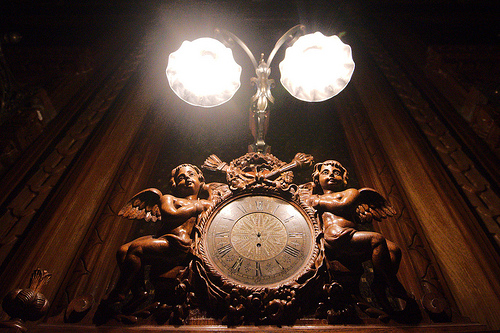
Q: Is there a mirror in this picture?
A: No, there are no mirrors.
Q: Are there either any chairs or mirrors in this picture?
A: No, there are no mirrors or chairs.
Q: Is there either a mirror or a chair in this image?
A: No, there are no mirrors or chairs.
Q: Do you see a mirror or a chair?
A: No, there are no mirrors or chairs.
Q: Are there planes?
A: No, there are no planes.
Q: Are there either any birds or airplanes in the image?
A: No, there are no airplanes or birds.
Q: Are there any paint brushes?
A: No, there are no paint brushes.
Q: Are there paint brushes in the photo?
A: No, there are no paint brushes.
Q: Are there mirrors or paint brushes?
A: No, there are no paint brushes or mirrors.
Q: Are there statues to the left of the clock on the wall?
A: Yes, there is a statue to the left of the clock.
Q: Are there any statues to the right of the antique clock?
A: No, the statue is to the left of the clock.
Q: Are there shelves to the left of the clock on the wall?
A: No, there is a statue to the left of the clock.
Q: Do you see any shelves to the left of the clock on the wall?
A: No, there is a statue to the left of the clock.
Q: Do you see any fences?
A: No, there are no fences.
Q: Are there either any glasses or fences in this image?
A: No, there are no fences or glasses.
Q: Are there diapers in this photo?
A: No, there are no diapers.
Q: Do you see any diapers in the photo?
A: No, there are no diapers.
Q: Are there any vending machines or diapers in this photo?
A: No, there are no diapers or vending machines.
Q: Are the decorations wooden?
A: Yes, the decorations are wooden.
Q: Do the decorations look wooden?
A: Yes, the decorations are wooden.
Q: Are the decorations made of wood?
A: Yes, the decorations are made of wood.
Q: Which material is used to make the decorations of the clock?
A: The decorations are made of wood.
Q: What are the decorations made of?
A: The decorations are made of wood.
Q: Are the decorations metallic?
A: No, the decorations are wooden.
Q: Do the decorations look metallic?
A: No, the decorations are wooden.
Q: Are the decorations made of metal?
A: No, the decorations are made of wood.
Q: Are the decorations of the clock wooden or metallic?
A: The decorations are wooden.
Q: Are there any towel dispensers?
A: No, there are no towel dispensers.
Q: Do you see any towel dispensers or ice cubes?
A: No, there are no towel dispensers or ice cubes.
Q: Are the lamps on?
A: Yes, the lamps are on.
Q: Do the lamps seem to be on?
A: Yes, the lamps are on.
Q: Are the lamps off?
A: No, the lamps are on.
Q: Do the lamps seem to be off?
A: No, the lamps are on.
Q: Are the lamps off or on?
A: The lamps are on.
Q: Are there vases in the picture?
A: No, there are no vases.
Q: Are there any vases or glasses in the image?
A: No, there are no vases or glasses.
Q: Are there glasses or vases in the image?
A: No, there are no vases or glasses.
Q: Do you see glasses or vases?
A: No, there are no vases or glasses.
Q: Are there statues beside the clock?
A: Yes, there is a statue beside the clock.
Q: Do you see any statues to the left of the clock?
A: Yes, there is a statue to the left of the clock.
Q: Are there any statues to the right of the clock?
A: No, the statue is to the left of the clock.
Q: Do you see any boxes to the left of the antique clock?
A: No, there is a statue to the left of the clock.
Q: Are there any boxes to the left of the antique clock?
A: No, there is a statue to the left of the clock.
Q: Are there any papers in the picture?
A: No, there are no papers.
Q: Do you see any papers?
A: No, there are no papers.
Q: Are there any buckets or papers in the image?
A: No, there are no papers or buckets.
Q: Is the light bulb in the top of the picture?
A: Yes, the light bulb is in the top of the image.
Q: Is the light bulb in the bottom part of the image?
A: No, the light bulb is in the top of the image.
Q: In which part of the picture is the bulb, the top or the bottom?
A: The bulb is in the top of the image.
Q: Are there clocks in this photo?
A: Yes, there is a clock.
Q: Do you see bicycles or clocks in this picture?
A: Yes, there is a clock.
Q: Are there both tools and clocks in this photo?
A: No, there is a clock but no tools.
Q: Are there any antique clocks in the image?
A: Yes, there is an antique clock.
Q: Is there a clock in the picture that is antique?
A: Yes, there is a clock that is antique.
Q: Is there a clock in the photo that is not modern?
A: Yes, there is a antique clock.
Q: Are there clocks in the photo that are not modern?
A: Yes, there is a antique clock.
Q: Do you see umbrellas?
A: No, there are no umbrellas.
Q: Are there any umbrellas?
A: No, there are no umbrellas.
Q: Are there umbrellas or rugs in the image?
A: No, there are no umbrellas or rugs.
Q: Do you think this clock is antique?
A: Yes, the clock is antique.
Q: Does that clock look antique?
A: Yes, the clock is antique.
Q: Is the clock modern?
A: No, the clock is antique.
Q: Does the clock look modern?
A: No, the clock is antique.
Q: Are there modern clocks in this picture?
A: No, there is a clock but it is antique.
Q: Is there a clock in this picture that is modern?
A: No, there is a clock but it is antique.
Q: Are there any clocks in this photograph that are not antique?
A: No, there is a clock but it is antique.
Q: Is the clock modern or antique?
A: The clock is antique.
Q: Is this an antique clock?
A: Yes, this is an antique clock.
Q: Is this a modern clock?
A: No, this is an antique clock.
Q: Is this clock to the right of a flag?
A: No, the clock is to the right of a statue.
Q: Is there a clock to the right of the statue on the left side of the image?
A: Yes, there is a clock to the right of the statue.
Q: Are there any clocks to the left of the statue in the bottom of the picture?
A: No, the clock is to the right of the statue.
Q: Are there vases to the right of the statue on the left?
A: No, there is a clock to the right of the statue.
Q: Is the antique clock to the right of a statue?
A: Yes, the clock is to the right of a statue.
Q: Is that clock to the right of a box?
A: No, the clock is to the right of a statue.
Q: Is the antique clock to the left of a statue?
A: No, the clock is to the right of a statue.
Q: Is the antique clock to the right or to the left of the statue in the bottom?
A: The clock is to the right of the statue.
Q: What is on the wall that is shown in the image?
A: The clock is on the wall.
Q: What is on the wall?
A: The clock is on the wall.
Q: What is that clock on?
A: The clock is on the wall.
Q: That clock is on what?
A: The clock is on the wall.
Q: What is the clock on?
A: The clock is on the wall.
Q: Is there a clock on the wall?
A: Yes, there is a clock on the wall.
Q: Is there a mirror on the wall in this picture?
A: No, there is a clock on the wall.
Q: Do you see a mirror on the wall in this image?
A: No, there is a clock on the wall.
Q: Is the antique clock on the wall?
A: Yes, the clock is on the wall.